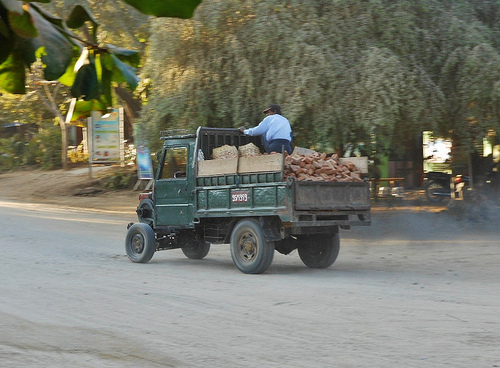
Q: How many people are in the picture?
A: 1.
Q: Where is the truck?
A: Street.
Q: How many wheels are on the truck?
A: 4.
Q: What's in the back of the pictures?
A: Trees.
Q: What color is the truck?
A: Green.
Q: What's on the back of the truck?
A: Logs.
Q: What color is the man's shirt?
A: Yellow.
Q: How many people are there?
A: One.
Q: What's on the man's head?
A: A Hat.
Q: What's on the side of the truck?
A: Numbers.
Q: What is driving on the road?
A: Green truck.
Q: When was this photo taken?
A: Daytime.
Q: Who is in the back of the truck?
A: A man.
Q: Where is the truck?
A: Roadway.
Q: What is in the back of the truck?
A: Bricks.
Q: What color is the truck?
A: Green.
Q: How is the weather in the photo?
A: Sunny and dry.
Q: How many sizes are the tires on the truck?
A: Two.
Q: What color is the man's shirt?
A: Light blue.